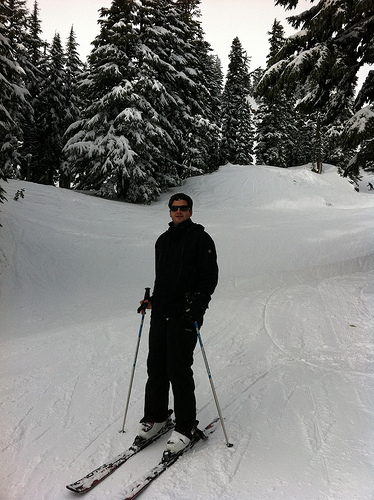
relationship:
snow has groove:
[240, 282, 364, 471] [263, 302, 300, 351]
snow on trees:
[78, 122, 129, 142] [87, 12, 254, 179]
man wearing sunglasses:
[103, 181, 205, 376] [161, 204, 214, 210]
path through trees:
[12, 167, 109, 235] [87, 12, 254, 179]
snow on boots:
[240, 282, 364, 471] [136, 420, 189, 451]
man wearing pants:
[103, 181, 205, 376] [132, 311, 207, 415]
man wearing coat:
[103, 181, 205, 376] [163, 234, 225, 307]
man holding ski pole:
[103, 181, 205, 376] [189, 316, 232, 446]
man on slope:
[103, 181, 205, 376] [229, 276, 308, 474]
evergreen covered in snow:
[201, 21, 351, 181] [240, 282, 364, 471]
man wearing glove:
[103, 181, 205, 376] [193, 308, 213, 327]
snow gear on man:
[161, 231, 187, 395] [103, 181, 205, 376]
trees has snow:
[87, 12, 254, 179] [78, 122, 129, 142]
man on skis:
[103, 181, 205, 376] [81, 461, 163, 488]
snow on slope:
[240, 282, 364, 471] [229, 276, 308, 474]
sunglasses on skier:
[161, 204, 214, 210] [126, 192, 232, 444]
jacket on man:
[138, 233, 216, 330] [103, 181, 205, 376]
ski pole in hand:
[189, 316, 232, 446] [182, 312, 203, 333]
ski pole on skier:
[189, 316, 232, 446] [126, 192, 232, 444]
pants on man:
[132, 311, 207, 415] [103, 181, 205, 376]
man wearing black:
[103, 181, 205, 376] [154, 235, 206, 340]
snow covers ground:
[240, 282, 364, 471] [13, 383, 346, 481]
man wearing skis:
[103, 181, 205, 376] [81, 461, 163, 488]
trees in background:
[87, 12, 254, 179] [24, 24, 340, 202]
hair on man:
[171, 192, 188, 203] [103, 181, 205, 376]